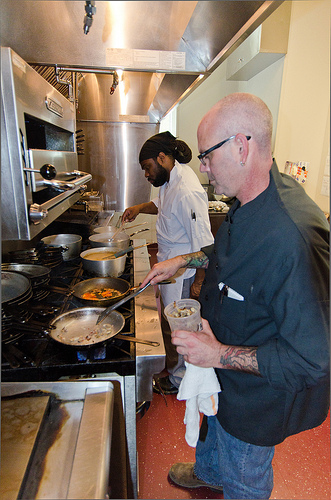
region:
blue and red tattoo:
[213, 348, 265, 372]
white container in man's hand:
[154, 294, 201, 330]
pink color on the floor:
[275, 451, 309, 475]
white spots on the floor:
[146, 435, 176, 455]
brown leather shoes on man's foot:
[165, 460, 214, 485]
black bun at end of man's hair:
[154, 131, 194, 164]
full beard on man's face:
[144, 153, 180, 192]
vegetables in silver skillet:
[75, 278, 126, 303]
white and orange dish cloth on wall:
[280, 157, 316, 185]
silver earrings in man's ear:
[235, 159, 247, 168]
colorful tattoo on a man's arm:
[218, 346, 259, 372]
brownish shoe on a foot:
[165, 459, 223, 489]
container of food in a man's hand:
[161, 297, 219, 367]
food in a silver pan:
[48, 305, 165, 348]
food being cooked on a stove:
[45, 306, 158, 361]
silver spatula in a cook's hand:
[93, 266, 170, 327]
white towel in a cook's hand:
[172, 332, 224, 447]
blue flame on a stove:
[74, 349, 109, 362]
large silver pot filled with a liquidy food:
[79, 239, 153, 276]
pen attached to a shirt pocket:
[213, 282, 230, 311]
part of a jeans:
[263, 459, 272, 471]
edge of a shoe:
[179, 475, 184, 482]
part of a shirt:
[250, 423, 264, 457]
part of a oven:
[136, 391, 139, 399]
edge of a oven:
[139, 363, 143, 368]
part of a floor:
[165, 440, 170, 446]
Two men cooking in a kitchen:
[118, 92, 330, 498]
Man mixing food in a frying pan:
[43, 92, 329, 497]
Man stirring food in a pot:
[88, 127, 216, 395]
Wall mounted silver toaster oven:
[0, 45, 91, 243]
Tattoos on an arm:
[217, 341, 259, 375]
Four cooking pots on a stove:
[38, 221, 152, 274]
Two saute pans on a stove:
[44, 273, 172, 348]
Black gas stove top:
[2, 234, 134, 376]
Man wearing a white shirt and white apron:
[119, 131, 214, 396]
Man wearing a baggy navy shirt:
[139, 91, 330, 498]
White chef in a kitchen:
[138, 92, 325, 497]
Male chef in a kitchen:
[143, 92, 327, 497]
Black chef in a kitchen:
[116, 129, 196, 302]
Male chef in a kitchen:
[118, 131, 198, 296]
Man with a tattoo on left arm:
[169, 317, 258, 372]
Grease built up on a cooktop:
[2, 389, 70, 496]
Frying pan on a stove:
[51, 305, 160, 350]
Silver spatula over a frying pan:
[96, 281, 159, 325]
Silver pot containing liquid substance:
[80, 246, 126, 275]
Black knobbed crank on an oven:
[23, 161, 57, 180]